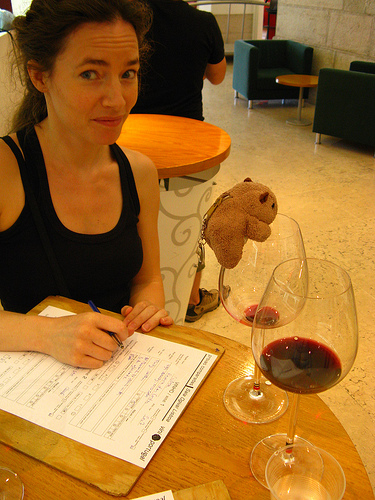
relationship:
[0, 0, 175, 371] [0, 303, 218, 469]
woman filling out form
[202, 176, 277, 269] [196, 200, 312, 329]
animal in wine glass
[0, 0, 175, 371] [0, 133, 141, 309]
woman in tank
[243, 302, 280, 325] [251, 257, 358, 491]
red wine in glass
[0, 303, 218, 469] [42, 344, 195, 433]
form in writing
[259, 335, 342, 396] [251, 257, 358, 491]
red wine in glass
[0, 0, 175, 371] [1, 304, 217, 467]
woman in application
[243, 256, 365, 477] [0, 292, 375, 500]
wine glass in round table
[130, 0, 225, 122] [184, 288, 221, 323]
man in shoes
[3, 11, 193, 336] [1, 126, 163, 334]
woman wearing tank top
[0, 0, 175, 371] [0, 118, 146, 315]
woman wearing tank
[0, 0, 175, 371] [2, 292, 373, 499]
woman sitting at round table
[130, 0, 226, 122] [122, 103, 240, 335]
man standing in front of table